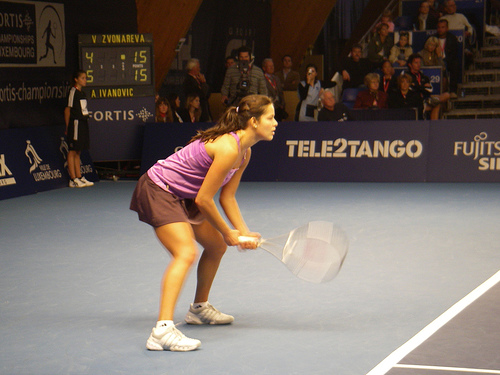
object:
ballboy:
[61, 67, 96, 188]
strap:
[227, 131, 241, 155]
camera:
[238, 79, 252, 91]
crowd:
[150, 0, 475, 122]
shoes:
[184, 305, 234, 328]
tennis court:
[0, 185, 495, 370]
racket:
[53, 22, 58, 37]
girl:
[130, 93, 277, 352]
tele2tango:
[285, 137, 423, 158]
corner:
[396, 346, 426, 367]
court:
[0, 169, 499, 374]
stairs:
[446, 17, 499, 120]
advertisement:
[34, 1, 67, 68]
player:
[39, 19, 59, 64]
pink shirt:
[147, 129, 248, 198]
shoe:
[145, 327, 201, 352]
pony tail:
[187, 104, 242, 144]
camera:
[240, 60, 250, 72]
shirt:
[391, 87, 421, 114]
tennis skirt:
[129, 171, 207, 227]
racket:
[238, 219, 350, 284]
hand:
[223, 230, 240, 247]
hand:
[241, 232, 261, 250]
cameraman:
[220, 46, 269, 107]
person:
[313, 89, 353, 122]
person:
[355, 72, 388, 119]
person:
[387, 74, 424, 118]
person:
[178, 95, 208, 123]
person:
[404, 53, 429, 93]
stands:
[330, 4, 492, 118]